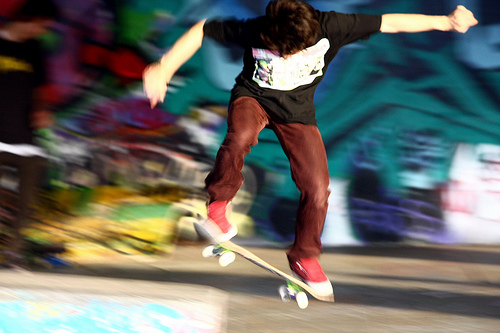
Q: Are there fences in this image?
A: No, there are no fences.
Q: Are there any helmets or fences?
A: No, there are no fences or helmets.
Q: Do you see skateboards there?
A: Yes, there is a skateboard.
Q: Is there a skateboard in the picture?
A: Yes, there is a skateboard.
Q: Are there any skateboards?
A: Yes, there is a skateboard.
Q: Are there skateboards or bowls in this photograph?
A: Yes, there is a skateboard.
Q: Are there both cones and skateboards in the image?
A: No, there is a skateboard but no cones.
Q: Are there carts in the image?
A: No, there are no carts.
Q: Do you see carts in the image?
A: No, there are no carts.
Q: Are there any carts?
A: No, there are no carts.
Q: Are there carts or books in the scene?
A: No, there are no carts or books.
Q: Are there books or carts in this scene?
A: No, there are no carts or books.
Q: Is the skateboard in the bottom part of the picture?
A: Yes, the skateboard is in the bottom of the image.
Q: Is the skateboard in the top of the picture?
A: No, the skateboard is in the bottom of the image.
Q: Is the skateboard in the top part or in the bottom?
A: The skateboard is in the bottom of the image.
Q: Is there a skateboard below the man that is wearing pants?
A: Yes, there is a skateboard below the man.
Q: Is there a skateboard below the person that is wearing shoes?
A: Yes, there is a skateboard below the man.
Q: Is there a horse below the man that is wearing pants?
A: No, there is a skateboard below the man.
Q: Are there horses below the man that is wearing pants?
A: No, there is a skateboard below the man.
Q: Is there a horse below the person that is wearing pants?
A: No, there is a skateboard below the man.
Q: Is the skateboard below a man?
A: Yes, the skateboard is below a man.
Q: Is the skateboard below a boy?
A: No, the skateboard is below a man.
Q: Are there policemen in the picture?
A: No, there are no policemen.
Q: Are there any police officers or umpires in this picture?
A: No, there are no police officers or umpires.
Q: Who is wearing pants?
A: The man is wearing pants.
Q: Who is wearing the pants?
A: The man is wearing pants.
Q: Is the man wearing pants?
A: Yes, the man is wearing pants.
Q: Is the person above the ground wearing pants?
A: Yes, the man is wearing pants.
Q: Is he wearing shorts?
A: No, the man is wearing pants.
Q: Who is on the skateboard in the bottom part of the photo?
A: The man is on the skateboard.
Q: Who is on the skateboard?
A: The man is on the skateboard.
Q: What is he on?
A: The man is on the skateboard.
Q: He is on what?
A: The man is on the skateboard.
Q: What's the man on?
A: The man is on the skateboard.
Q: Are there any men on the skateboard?
A: Yes, there is a man on the skateboard.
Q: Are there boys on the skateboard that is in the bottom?
A: No, there is a man on the skateboard.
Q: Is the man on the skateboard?
A: Yes, the man is on the skateboard.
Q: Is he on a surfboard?
A: No, the man is on the skateboard.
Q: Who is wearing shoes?
A: The man is wearing shoes.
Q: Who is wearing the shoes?
A: The man is wearing shoes.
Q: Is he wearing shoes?
A: Yes, the man is wearing shoes.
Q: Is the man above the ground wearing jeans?
A: No, the man is wearing shoes.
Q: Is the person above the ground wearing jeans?
A: No, the man is wearing shoes.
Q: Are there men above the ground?
A: Yes, there is a man above the ground.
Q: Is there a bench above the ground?
A: No, there is a man above the ground.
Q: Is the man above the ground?
A: Yes, the man is above the ground.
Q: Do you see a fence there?
A: No, there are no fences.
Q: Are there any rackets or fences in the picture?
A: No, there are no fences or rackets.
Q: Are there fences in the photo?
A: No, there are no fences.